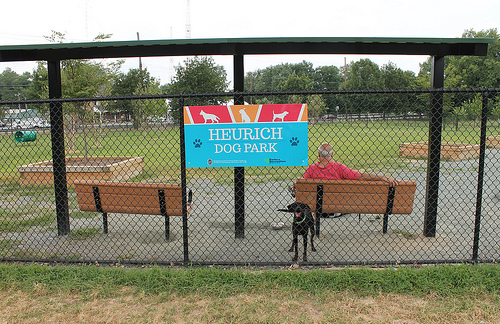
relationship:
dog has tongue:
[277, 201, 319, 265] [293, 212, 301, 220]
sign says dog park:
[183, 104, 312, 170] [213, 142, 280, 154]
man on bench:
[288, 142, 399, 195] [290, 178, 420, 232]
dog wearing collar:
[277, 201, 319, 265] [291, 216, 310, 224]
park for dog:
[0, 116, 499, 263] [277, 201, 319, 265]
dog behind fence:
[277, 201, 319, 265] [1, 87, 499, 267]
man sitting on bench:
[288, 142, 399, 195] [290, 178, 420, 232]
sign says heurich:
[183, 104, 312, 170] [207, 124, 286, 142]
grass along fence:
[1, 263, 497, 293] [1, 87, 499, 267]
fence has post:
[1, 87, 499, 267] [177, 97, 192, 263]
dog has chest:
[277, 201, 319, 265] [290, 220, 308, 235]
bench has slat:
[73, 178, 196, 239] [77, 192, 185, 208]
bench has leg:
[290, 178, 420, 232] [382, 213, 391, 234]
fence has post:
[1, 87, 499, 267] [473, 94, 491, 261]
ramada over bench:
[0, 35, 490, 241] [290, 178, 420, 232]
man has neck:
[288, 142, 399, 195] [319, 156, 330, 164]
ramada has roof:
[0, 35, 490, 241] [1, 34, 494, 60]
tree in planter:
[30, 59, 124, 157] [19, 155, 147, 188]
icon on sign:
[288, 134, 301, 149] [183, 104, 312, 170]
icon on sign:
[190, 137, 202, 149] [183, 104, 312, 170]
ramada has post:
[0, 35, 490, 241] [422, 56, 446, 235]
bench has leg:
[73, 178, 196, 239] [163, 216, 171, 241]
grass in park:
[0, 121, 500, 169] [0, 116, 499, 263]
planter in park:
[395, 137, 484, 160] [0, 116, 499, 263]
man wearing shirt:
[288, 142, 399, 195] [301, 159, 360, 180]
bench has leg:
[73, 178, 196, 239] [100, 211, 110, 233]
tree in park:
[165, 56, 236, 120] [0, 116, 499, 263]